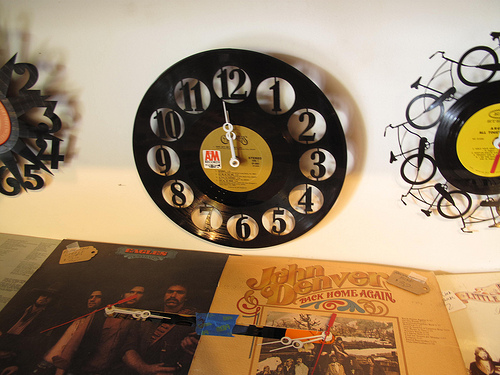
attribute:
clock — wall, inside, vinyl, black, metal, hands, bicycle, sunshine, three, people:
[121, 36, 382, 273]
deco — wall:
[0, 40, 92, 208]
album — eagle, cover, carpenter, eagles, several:
[22, 216, 239, 372]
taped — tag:
[286, 255, 420, 331]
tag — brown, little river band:
[262, 255, 419, 329]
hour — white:
[189, 73, 300, 189]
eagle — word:
[60, 287, 194, 347]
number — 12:
[206, 49, 260, 114]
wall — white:
[56, 14, 412, 306]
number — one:
[257, 75, 311, 127]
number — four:
[286, 169, 343, 227]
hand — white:
[207, 108, 259, 168]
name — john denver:
[251, 264, 361, 318]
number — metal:
[292, 106, 333, 152]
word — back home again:
[288, 272, 401, 335]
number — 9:
[145, 144, 177, 180]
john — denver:
[265, 254, 345, 318]